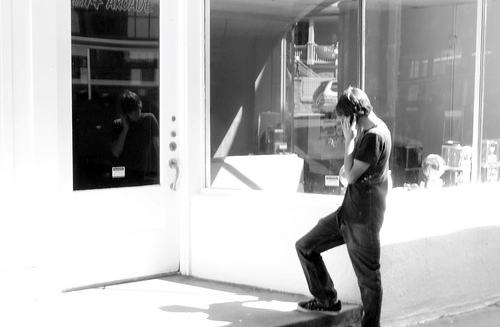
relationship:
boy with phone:
[291, 78, 395, 320] [348, 112, 366, 132]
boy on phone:
[291, 78, 395, 320] [348, 112, 366, 132]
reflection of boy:
[103, 89, 158, 177] [291, 78, 395, 320]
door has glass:
[47, 5, 192, 265] [70, 10, 165, 193]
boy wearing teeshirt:
[291, 78, 395, 320] [328, 127, 397, 226]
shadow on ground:
[162, 294, 299, 326] [121, 268, 299, 324]